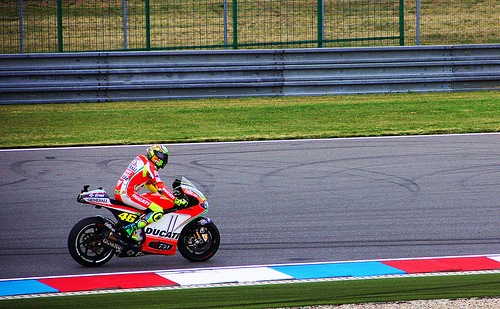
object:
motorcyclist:
[112, 142, 188, 243]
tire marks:
[1, 140, 499, 260]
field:
[4, 3, 497, 53]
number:
[117, 210, 137, 223]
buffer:
[2, 251, 499, 298]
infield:
[3, 274, 498, 308]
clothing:
[115, 153, 189, 240]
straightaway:
[2, 130, 499, 277]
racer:
[112, 143, 189, 243]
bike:
[67, 173, 220, 266]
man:
[108, 140, 189, 245]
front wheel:
[172, 216, 222, 265]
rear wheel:
[62, 207, 122, 270]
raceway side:
[2, 240, 498, 307]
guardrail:
[1, 47, 499, 92]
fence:
[6, 5, 498, 43]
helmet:
[144, 140, 174, 170]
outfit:
[115, 160, 167, 236]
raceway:
[1, 145, 499, 299]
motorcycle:
[81, 145, 228, 259]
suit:
[115, 151, 182, 247]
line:
[2, 248, 499, 298]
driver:
[113, 140, 191, 249]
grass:
[0, 88, 497, 152]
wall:
[0, 39, 499, 110]